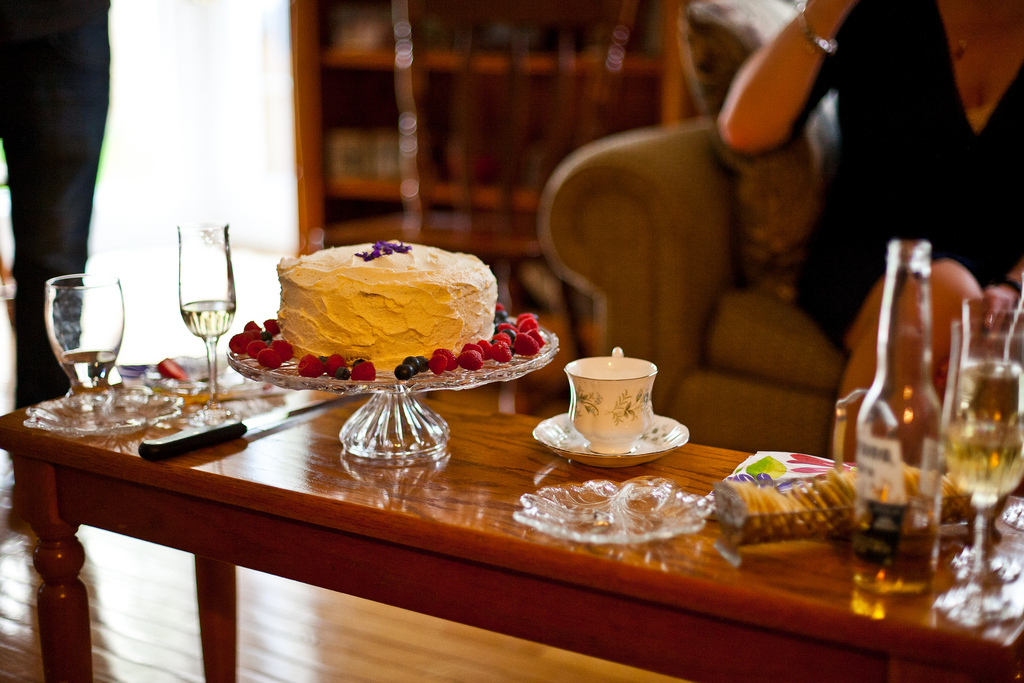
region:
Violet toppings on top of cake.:
[351, 240, 419, 261]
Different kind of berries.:
[289, 351, 376, 380]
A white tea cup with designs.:
[561, 345, 659, 451]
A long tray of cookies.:
[708, 467, 1000, 566]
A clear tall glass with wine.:
[174, 221, 239, 421]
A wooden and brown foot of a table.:
[11, 455, 91, 680]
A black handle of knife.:
[131, 417, 246, 462]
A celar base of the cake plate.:
[334, 393, 453, 458]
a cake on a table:
[257, 171, 578, 367]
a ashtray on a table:
[517, 446, 759, 560]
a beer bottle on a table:
[772, 227, 997, 630]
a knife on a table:
[99, 236, 514, 522]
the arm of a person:
[683, 1, 930, 192]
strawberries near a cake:
[345, 294, 538, 390]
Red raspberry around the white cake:
[346, 356, 375, 377]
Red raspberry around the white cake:
[298, 347, 324, 373]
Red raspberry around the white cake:
[251, 341, 283, 373]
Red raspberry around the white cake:
[454, 347, 481, 368]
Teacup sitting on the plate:
[563, 341, 662, 455]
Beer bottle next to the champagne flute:
[839, 234, 950, 598]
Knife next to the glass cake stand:
[138, 391, 334, 461]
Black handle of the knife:
[138, 408, 247, 462]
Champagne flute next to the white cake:
[168, 215, 241, 408]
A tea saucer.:
[533, 405, 702, 462]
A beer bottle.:
[836, 218, 934, 624]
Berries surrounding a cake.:
[238, 304, 549, 375]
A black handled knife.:
[141, 370, 288, 469]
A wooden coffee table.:
[16, 318, 1015, 670]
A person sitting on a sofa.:
[535, 0, 1022, 497]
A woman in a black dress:
[703, 1, 1023, 445]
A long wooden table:
[22, 348, 1018, 680]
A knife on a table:
[133, 393, 361, 466]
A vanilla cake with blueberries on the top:
[262, 241, 501, 360]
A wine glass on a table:
[172, 221, 239, 406]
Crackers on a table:
[716, 469, 952, 558]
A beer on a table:
[846, 234, 963, 624]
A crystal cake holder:
[221, 314, 569, 474]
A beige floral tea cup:
[559, 342, 662, 451]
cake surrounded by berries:
[226, 233, 562, 465]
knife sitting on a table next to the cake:
[134, 391, 362, 458]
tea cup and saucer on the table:
[531, 345, 690, 469]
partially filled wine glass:
[169, 217, 233, 402]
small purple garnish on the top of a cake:
[351, 236, 416, 269]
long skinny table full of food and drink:
[2, 350, 1014, 677]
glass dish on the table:
[510, 474, 713, 552]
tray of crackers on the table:
[708, 470, 968, 568]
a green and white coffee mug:
[563, 341, 659, 444]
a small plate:
[533, 408, 688, 463]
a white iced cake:
[270, 227, 499, 364]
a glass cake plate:
[222, 331, 562, 461]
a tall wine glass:
[174, 225, 248, 409]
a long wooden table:
[4, 342, 1017, 679]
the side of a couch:
[529, 98, 881, 460]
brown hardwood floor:
[0, 534, 435, 680]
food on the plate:
[279, 154, 580, 412]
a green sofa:
[561, 135, 963, 423]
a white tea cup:
[543, 358, 679, 457]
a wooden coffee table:
[0, 367, 1010, 680]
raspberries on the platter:
[427, 347, 501, 370]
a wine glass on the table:
[177, 225, 239, 404]